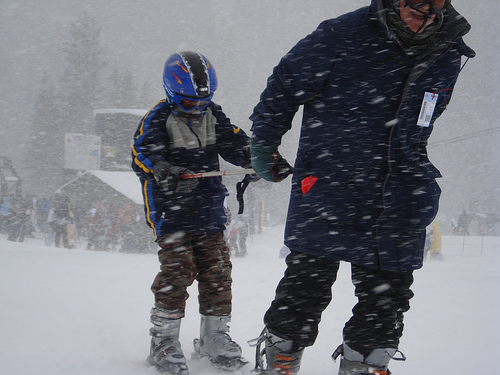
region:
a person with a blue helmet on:
[132, 51, 249, 371]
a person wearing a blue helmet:
[138, 55, 244, 370]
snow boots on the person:
[146, 298, 246, 370]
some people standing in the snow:
[3, 190, 135, 250]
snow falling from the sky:
[21, 52, 131, 137]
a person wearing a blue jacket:
[251, 0, 457, 374]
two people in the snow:
[133, 2, 461, 374]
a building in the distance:
[61, 170, 153, 220]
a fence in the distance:
[446, 230, 488, 252]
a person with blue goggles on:
[131, 60, 271, 372]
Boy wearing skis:
[140, 302, 267, 374]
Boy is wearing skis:
[142, 301, 259, 373]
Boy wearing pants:
[151, 220, 236, 320]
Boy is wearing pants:
[148, 226, 241, 316]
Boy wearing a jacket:
[129, 95, 286, 232]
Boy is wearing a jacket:
[128, 100, 283, 235]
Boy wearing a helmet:
[162, 47, 224, 117]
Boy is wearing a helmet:
[159, 47, 219, 117]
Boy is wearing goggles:
[159, 80, 220, 110]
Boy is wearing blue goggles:
[160, 75, 220, 113]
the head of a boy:
[148, 8, 292, 129]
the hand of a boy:
[137, 153, 218, 195]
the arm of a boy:
[117, 85, 188, 233]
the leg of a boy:
[141, 229, 211, 350]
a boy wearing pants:
[140, 202, 264, 330]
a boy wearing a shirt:
[95, 96, 255, 303]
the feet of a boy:
[142, 315, 260, 373]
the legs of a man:
[241, 183, 432, 341]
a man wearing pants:
[250, 185, 485, 339]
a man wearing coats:
[257, 5, 435, 255]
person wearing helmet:
[117, 46, 279, 370]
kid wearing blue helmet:
[117, 50, 291, 374]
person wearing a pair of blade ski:
[118, 39, 297, 374]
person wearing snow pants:
[112, 43, 285, 371]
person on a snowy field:
[115, 35, 288, 373]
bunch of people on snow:
[9, 166, 257, 259]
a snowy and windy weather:
[14, 15, 144, 122]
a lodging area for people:
[51, 165, 224, 257]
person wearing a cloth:
[247, 0, 475, 374]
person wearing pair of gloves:
[245, 0, 468, 374]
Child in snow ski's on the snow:
[127, 48, 272, 373]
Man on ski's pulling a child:
[250, 1, 477, 373]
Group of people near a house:
[0, 187, 255, 258]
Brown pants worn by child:
[155, 223, 235, 313]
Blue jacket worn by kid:
[130, 93, 293, 235]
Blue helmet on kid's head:
[158, 49, 220, 97]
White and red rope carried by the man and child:
[168, 154, 292, 187]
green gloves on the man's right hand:
[250, 141, 291, 182]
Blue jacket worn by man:
[249, 5, 475, 269]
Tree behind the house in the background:
[23, 11, 150, 197]